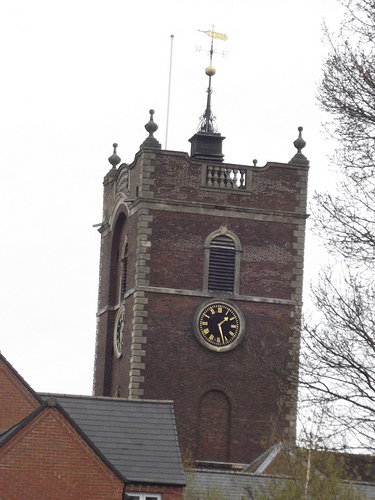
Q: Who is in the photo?
A: No one.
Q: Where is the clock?
A: On the tower.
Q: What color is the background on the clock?
A: Black.